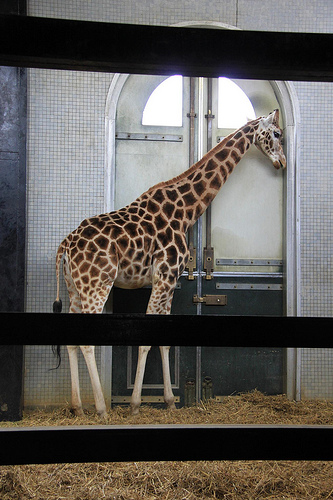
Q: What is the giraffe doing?
A: Standing.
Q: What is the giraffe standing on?
A: Straw.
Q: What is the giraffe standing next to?
A: The door.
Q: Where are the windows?
A: Near the top of the door.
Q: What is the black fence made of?
A: Wood.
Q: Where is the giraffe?
A: Likely at a zoo.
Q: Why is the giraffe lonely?
A: There are no other giraffes in the room.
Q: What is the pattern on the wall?
A: Many small squares.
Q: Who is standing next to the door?
A: A giraffe.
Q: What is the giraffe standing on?
A: Straw.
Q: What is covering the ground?
A: Straw.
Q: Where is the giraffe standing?
A: Near the door.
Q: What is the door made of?
A: Metal.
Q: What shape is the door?
A: Arched.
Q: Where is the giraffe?
A: In a zoo.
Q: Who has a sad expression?
A: The giraffe.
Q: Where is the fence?
A: On the other side of the enclosure.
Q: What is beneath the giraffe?
A: Hay.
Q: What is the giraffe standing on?
A: Hay.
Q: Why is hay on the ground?
A: For comfort.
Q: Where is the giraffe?
A: Inside building.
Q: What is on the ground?
A: Hay.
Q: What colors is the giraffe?
A: White and brown.